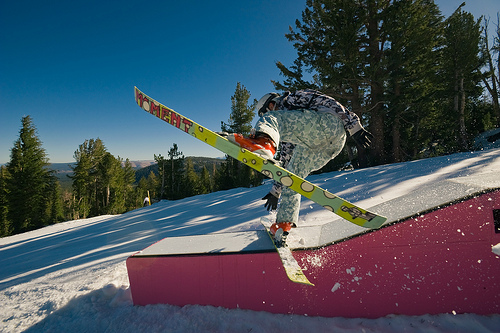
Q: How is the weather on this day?
A: It is clear.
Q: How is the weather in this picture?
A: It is clear.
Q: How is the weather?
A: It is clear.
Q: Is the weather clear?
A: Yes, it is clear.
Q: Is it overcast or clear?
A: It is clear.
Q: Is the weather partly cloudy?
A: No, it is clear.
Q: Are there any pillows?
A: No, there are no pillows.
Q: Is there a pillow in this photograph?
A: No, there are no pillows.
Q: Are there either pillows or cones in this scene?
A: No, there are no pillows or cones.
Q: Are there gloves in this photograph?
A: Yes, there are gloves.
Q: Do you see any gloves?
A: Yes, there are gloves.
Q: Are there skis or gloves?
A: Yes, there are gloves.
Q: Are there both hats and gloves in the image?
A: No, there are gloves but no hats.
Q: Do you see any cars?
A: No, there are no cars.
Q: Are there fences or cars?
A: No, there are no cars or fences.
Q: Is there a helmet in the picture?
A: Yes, there is a helmet.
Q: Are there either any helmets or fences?
A: Yes, there is a helmet.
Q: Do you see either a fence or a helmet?
A: Yes, there is a helmet.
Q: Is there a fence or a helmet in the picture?
A: Yes, there is a helmet.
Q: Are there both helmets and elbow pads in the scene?
A: No, there is a helmet but no elbow pads.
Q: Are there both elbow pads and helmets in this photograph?
A: No, there is a helmet but no elbow pads.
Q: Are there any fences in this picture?
A: No, there are no fences.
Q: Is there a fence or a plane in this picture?
A: No, there are no fences or airplanes.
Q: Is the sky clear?
A: Yes, the sky is clear.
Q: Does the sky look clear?
A: Yes, the sky is clear.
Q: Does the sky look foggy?
A: No, the sky is clear.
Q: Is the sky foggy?
A: No, the sky is clear.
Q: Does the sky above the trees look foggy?
A: No, the sky is clear.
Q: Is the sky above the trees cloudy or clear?
A: The sky is clear.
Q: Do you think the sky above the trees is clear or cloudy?
A: The sky is clear.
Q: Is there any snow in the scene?
A: Yes, there is snow.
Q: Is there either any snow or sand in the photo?
A: Yes, there is snow.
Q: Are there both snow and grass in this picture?
A: No, there is snow but no grass.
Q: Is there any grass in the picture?
A: No, there is no grass.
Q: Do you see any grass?
A: No, there is no grass.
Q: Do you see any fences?
A: No, there are no fences.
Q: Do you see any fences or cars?
A: No, there are no fences or cars.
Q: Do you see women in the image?
A: No, there are no women.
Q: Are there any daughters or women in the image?
A: No, there are no women or daughters.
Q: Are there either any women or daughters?
A: No, there are no women or daughters.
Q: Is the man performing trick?
A: Yes, the man is performing trick.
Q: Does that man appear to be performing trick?
A: Yes, the man is performing trick.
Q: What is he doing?
A: The man is performing trick.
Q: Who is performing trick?
A: The man is performing trick.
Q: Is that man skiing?
A: No, the man is performing trick.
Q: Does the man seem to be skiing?
A: No, the man is performing trick.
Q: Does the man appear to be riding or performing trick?
A: The man is performing trick.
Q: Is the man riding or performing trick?
A: The man is performing trick.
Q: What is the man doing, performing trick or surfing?
A: The man is performing trick.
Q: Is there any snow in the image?
A: Yes, there is snow.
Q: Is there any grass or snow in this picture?
A: Yes, there is snow.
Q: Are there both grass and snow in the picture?
A: No, there is snow but no grass.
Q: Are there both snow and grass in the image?
A: No, there is snow but no grass.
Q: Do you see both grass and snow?
A: No, there is snow but no grass.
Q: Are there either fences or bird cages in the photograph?
A: No, there are no fences or bird cages.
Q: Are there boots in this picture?
A: Yes, there are boots.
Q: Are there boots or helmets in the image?
A: Yes, there are boots.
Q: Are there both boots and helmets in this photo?
A: Yes, there are both boots and a helmet.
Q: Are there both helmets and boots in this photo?
A: Yes, there are both boots and a helmet.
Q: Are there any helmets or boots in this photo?
A: Yes, there are boots.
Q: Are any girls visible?
A: No, there are no girls.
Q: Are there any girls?
A: No, there are no girls.